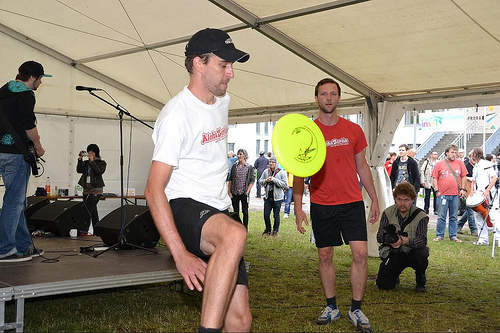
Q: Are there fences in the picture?
A: No, there are no fences.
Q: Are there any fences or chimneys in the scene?
A: No, there are no fences or chimneys.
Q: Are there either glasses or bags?
A: No, there are no glasses or bags.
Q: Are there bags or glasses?
A: No, there are no glasses or bags.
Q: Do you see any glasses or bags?
A: No, there are no glasses or bags.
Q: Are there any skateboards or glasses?
A: No, there are no glasses or skateboards.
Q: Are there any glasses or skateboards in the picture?
A: No, there are no glasses or skateboards.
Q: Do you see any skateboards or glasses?
A: No, there are no glasses or skateboards.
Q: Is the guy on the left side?
A: Yes, the guy is on the left of the image.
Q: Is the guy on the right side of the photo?
A: No, the guy is on the left of the image.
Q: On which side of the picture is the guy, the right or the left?
A: The guy is on the left of the image.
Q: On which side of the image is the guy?
A: The guy is on the left of the image.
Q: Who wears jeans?
A: The guy wears jeans.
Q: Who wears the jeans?
A: The guy wears jeans.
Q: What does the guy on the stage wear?
A: The guy wears jeans.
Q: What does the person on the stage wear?
A: The guy wears jeans.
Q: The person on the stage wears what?
A: The guy wears jeans.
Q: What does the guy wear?
A: The guy wears jeans.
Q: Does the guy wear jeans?
A: Yes, the guy wears jeans.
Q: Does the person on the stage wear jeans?
A: Yes, the guy wears jeans.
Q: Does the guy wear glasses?
A: No, the guy wears jeans.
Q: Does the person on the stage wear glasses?
A: No, the guy wears jeans.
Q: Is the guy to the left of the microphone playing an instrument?
A: Yes, the guy is playing an instrument.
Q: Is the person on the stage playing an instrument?
A: Yes, the guy is playing an instrument.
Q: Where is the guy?
A: The guy is on the stage.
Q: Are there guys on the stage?
A: Yes, there is a guy on the stage.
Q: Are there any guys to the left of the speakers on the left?
A: Yes, there is a guy to the left of the speakers.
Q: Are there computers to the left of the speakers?
A: No, there is a guy to the left of the speakers.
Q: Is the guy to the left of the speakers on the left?
A: Yes, the guy is to the left of the speakers.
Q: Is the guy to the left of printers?
A: No, the guy is to the left of the speakers.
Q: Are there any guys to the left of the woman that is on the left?
A: Yes, there is a guy to the left of the woman.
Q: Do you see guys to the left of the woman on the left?
A: Yes, there is a guy to the left of the woman.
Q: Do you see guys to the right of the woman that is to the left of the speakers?
A: No, the guy is to the left of the woman.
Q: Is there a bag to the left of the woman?
A: No, there is a guy to the left of the woman.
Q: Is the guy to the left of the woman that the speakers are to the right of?
A: Yes, the guy is to the left of the woman.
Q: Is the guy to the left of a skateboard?
A: No, the guy is to the left of the woman.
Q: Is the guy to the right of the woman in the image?
A: No, the guy is to the left of the woman.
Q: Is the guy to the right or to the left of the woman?
A: The guy is to the left of the woman.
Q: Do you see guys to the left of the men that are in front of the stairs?
A: Yes, there is a guy to the left of the men.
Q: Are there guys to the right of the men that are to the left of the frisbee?
A: No, the guy is to the left of the men.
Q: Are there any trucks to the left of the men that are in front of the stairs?
A: No, there is a guy to the left of the men.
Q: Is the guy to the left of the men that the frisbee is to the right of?
A: Yes, the guy is to the left of the men.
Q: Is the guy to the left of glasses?
A: No, the guy is to the left of the men.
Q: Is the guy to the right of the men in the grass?
A: No, the guy is to the left of the men.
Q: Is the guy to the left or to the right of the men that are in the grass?
A: The guy is to the left of the men.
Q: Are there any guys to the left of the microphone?
A: Yes, there is a guy to the left of the microphone.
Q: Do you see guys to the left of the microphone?
A: Yes, there is a guy to the left of the microphone.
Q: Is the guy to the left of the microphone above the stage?
A: Yes, the guy is to the left of the microphone.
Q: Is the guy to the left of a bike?
A: No, the guy is to the left of the microphone.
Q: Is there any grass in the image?
A: Yes, there is grass.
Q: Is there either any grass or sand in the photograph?
A: Yes, there is grass.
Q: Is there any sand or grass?
A: Yes, there is grass.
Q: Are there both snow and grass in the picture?
A: No, there is grass but no snow.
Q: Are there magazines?
A: No, there are no magazines.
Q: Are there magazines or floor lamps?
A: No, there are no magazines or floor lamps.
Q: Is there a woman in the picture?
A: Yes, there is a woman.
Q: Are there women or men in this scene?
A: Yes, there is a woman.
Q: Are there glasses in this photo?
A: No, there are no glasses.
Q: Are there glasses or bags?
A: No, there are no glasses or bags.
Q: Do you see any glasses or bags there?
A: No, there are no glasses or bags.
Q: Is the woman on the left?
A: Yes, the woman is on the left of the image.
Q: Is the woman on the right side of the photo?
A: No, the woman is on the left of the image.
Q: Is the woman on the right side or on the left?
A: The woman is on the left of the image.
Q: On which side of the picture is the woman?
A: The woman is on the left of the image.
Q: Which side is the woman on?
A: The woman is on the left of the image.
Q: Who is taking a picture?
A: The woman is taking a picture.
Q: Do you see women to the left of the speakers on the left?
A: Yes, there is a woman to the left of the speakers.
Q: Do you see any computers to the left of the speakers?
A: No, there is a woman to the left of the speakers.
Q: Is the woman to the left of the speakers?
A: Yes, the woman is to the left of the speakers.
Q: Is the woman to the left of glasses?
A: No, the woman is to the left of the speakers.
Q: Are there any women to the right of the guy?
A: Yes, there is a woman to the right of the guy.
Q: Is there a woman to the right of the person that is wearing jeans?
A: Yes, there is a woman to the right of the guy.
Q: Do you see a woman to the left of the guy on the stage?
A: No, the woman is to the right of the guy.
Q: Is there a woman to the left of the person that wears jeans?
A: No, the woman is to the right of the guy.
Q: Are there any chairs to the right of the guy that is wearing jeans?
A: No, there is a woman to the right of the guy.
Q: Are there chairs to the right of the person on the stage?
A: No, there is a woman to the right of the guy.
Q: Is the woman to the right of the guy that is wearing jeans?
A: Yes, the woman is to the right of the guy.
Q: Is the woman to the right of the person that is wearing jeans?
A: Yes, the woman is to the right of the guy.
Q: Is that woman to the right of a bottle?
A: No, the woman is to the right of the guy.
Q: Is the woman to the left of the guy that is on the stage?
A: No, the woman is to the right of the guy.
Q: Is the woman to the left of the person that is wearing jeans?
A: No, the woman is to the right of the guy.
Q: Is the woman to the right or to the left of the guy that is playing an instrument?
A: The woman is to the right of the guy.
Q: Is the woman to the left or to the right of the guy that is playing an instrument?
A: The woman is to the right of the guy.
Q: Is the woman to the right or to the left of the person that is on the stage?
A: The woman is to the right of the guy.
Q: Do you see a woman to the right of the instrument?
A: Yes, there is a woman to the right of the instrument.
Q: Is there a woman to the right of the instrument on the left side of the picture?
A: Yes, there is a woman to the right of the instrument.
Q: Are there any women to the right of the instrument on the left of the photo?
A: Yes, there is a woman to the right of the instrument.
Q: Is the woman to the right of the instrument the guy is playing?
A: Yes, the woman is to the right of the instrument.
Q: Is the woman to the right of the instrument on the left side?
A: Yes, the woman is to the right of the instrument.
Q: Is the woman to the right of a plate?
A: No, the woman is to the right of the instrument.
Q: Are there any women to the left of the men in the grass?
A: Yes, there is a woman to the left of the men.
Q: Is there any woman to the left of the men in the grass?
A: Yes, there is a woman to the left of the men.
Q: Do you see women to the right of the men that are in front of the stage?
A: No, the woman is to the left of the men.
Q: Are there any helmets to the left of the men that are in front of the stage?
A: No, there is a woman to the left of the men.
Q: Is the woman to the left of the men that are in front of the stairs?
A: Yes, the woman is to the left of the men.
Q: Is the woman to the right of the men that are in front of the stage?
A: No, the woman is to the left of the men.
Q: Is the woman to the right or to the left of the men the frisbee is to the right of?
A: The woman is to the left of the men.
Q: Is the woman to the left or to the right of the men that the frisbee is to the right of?
A: The woman is to the left of the men.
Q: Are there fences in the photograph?
A: No, there are no fences.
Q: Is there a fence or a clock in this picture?
A: No, there are no fences or clocks.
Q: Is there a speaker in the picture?
A: Yes, there are speakers.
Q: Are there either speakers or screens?
A: Yes, there are speakers.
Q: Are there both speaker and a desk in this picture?
A: No, there are speakers but no desks.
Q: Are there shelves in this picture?
A: No, there are no shelves.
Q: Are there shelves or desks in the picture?
A: No, there are no shelves or desks.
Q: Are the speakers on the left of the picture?
A: Yes, the speakers are on the left of the image.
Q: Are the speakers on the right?
A: No, the speakers are on the left of the image.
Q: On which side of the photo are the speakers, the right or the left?
A: The speakers are on the left of the image.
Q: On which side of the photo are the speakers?
A: The speakers are on the left of the image.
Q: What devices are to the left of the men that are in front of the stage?
A: The devices are speakers.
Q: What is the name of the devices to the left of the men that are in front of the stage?
A: The devices are speakers.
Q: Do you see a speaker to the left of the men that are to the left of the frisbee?
A: Yes, there are speakers to the left of the men.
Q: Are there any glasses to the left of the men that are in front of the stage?
A: No, there are speakers to the left of the men.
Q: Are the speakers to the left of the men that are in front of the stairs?
A: Yes, the speakers are to the left of the men.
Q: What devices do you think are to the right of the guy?
A: The devices are speakers.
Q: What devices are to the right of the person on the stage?
A: The devices are speakers.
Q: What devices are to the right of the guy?
A: The devices are speakers.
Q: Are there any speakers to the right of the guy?
A: Yes, there are speakers to the right of the guy.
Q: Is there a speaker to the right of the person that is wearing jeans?
A: Yes, there are speakers to the right of the guy.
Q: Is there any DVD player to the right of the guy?
A: No, there are speakers to the right of the guy.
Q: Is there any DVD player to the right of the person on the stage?
A: No, there are speakers to the right of the guy.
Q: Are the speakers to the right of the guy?
A: Yes, the speakers are to the right of the guy.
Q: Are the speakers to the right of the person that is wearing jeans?
A: Yes, the speakers are to the right of the guy.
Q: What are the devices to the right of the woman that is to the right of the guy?
A: The devices are speakers.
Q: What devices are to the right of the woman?
A: The devices are speakers.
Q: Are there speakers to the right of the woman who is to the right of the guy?
A: Yes, there are speakers to the right of the woman.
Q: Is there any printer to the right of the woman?
A: No, there are speakers to the right of the woman.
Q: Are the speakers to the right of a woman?
A: Yes, the speakers are to the right of a woman.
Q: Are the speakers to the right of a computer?
A: No, the speakers are to the right of a woman.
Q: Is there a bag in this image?
A: No, there are no bags.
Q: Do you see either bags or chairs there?
A: No, there are no bags or chairs.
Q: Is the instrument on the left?
A: Yes, the instrument is on the left of the image.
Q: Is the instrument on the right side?
A: No, the instrument is on the left of the image.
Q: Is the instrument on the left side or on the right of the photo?
A: The instrument is on the left of the image.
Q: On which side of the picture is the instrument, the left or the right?
A: The instrument is on the left of the image.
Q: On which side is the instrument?
A: The instrument is on the left of the image.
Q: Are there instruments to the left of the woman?
A: Yes, there is an instrument to the left of the woman.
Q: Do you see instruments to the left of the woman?
A: Yes, there is an instrument to the left of the woman.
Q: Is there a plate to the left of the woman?
A: No, there is an instrument to the left of the woman.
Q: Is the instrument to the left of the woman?
A: Yes, the instrument is to the left of the woman.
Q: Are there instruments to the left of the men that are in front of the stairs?
A: Yes, there is an instrument to the left of the men.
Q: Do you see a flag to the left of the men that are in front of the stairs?
A: No, there is an instrument to the left of the men.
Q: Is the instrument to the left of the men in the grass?
A: Yes, the instrument is to the left of the men.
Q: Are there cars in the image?
A: No, there are no cars.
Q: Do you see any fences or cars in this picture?
A: No, there are no cars or fences.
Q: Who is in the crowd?
A: The people are in the crowd.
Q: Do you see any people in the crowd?
A: Yes, there are people in the crowd.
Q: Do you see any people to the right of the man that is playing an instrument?
A: Yes, there are people to the right of the man.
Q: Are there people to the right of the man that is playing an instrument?
A: Yes, there are people to the right of the man.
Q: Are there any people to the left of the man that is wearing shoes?
A: No, the people are to the right of the man.